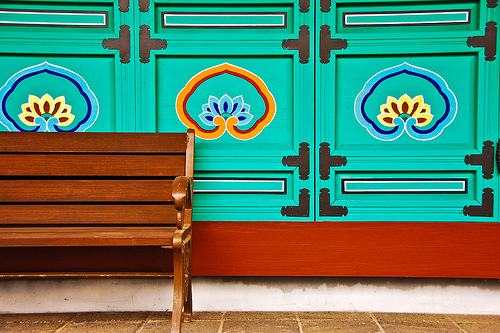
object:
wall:
[0, 2, 500, 313]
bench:
[0, 128, 198, 333]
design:
[354, 61, 459, 141]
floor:
[0, 311, 500, 333]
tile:
[0, 311, 500, 333]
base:
[0, 222, 500, 279]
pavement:
[0, 310, 499, 333]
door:
[4, 0, 500, 279]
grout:
[0, 312, 500, 333]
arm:
[171, 176, 193, 251]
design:
[175, 62, 276, 141]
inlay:
[281, 25, 311, 64]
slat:
[0, 132, 188, 154]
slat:
[0, 155, 186, 176]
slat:
[0, 179, 173, 201]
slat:
[0, 204, 184, 224]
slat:
[0, 227, 175, 248]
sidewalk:
[0, 312, 500, 333]